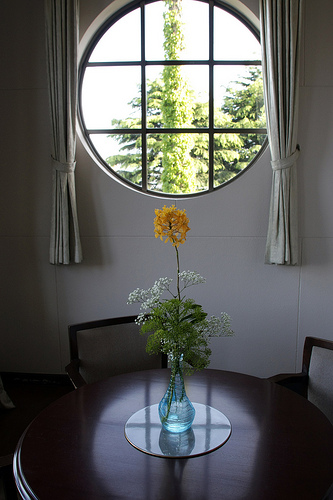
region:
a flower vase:
[125, 266, 218, 484]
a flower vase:
[163, 334, 237, 485]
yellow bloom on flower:
[150, 209, 201, 252]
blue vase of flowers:
[122, 198, 212, 439]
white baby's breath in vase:
[205, 314, 234, 348]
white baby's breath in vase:
[177, 269, 209, 292]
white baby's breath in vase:
[156, 278, 173, 297]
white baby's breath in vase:
[130, 291, 149, 306]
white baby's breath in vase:
[133, 313, 149, 328]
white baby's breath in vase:
[140, 295, 156, 307]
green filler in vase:
[144, 337, 165, 355]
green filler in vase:
[140, 323, 160, 331]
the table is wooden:
[73, 283, 270, 483]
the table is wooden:
[82, 342, 224, 459]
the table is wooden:
[42, 310, 211, 486]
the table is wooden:
[92, 341, 208, 484]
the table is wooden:
[33, 274, 290, 474]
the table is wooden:
[76, 299, 240, 488]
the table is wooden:
[77, 320, 199, 479]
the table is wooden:
[62, 294, 249, 499]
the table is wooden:
[40, 301, 203, 490]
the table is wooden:
[81, 305, 213, 492]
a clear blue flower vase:
[155, 360, 194, 433]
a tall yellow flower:
[150, 205, 191, 251]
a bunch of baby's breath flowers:
[126, 269, 231, 370]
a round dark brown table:
[12, 356, 331, 498]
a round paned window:
[78, 0, 271, 199]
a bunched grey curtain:
[40, 0, 88, 271]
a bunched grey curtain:
[254, 0, 302, 265]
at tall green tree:
[159, 0, 187, 195]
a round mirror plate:
[125, 399, 230, 457]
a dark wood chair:
[59, 314, 180, 393]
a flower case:
[146, 308, 185, 397]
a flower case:
[117, 250, 216, 473]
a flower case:
[142, 323, 208, 467]